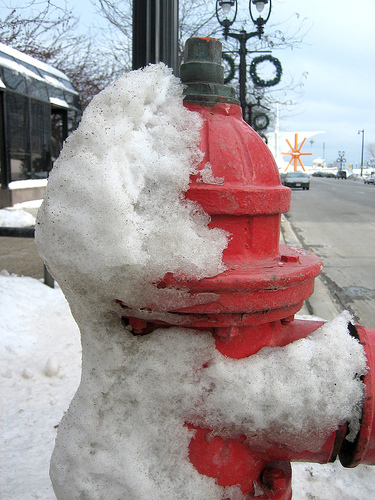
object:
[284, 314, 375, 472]
pipe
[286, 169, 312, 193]
car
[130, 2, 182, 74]
pole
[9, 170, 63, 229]
sidewalks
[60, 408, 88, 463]
snow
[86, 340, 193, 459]
snow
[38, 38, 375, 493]
hydrant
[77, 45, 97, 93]
branches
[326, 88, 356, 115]
clouds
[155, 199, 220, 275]
snow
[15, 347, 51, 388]
snow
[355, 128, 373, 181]
lamp post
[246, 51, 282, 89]
wreath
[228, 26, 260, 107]
post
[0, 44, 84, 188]
building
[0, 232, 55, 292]
sidewalk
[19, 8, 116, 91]
trees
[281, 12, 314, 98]
sky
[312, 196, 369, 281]
road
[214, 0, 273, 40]
light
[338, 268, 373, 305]
road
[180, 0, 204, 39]
tree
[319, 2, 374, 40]
sky